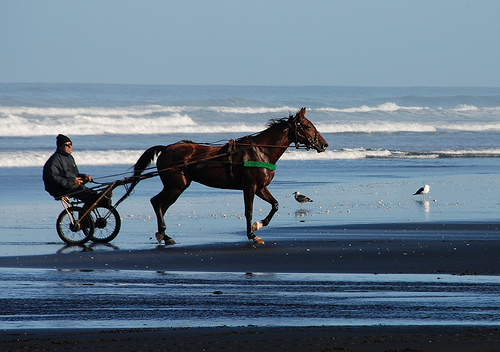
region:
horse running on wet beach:
[132, 110, 310, 242]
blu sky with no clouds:
[7, 12, 78, 56]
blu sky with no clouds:
[24, 53, 100, 69]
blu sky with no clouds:
[46, 20, 103, 82]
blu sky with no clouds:
[99, 10, 174, 60]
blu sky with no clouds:
[158, 40, 222, 70]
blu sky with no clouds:
[255, 20, 356, 91]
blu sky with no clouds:
[380, 12, 449, 47]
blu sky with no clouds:
[398, 3, 487, 74]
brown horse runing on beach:
[124, 105, 313, 237]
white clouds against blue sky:
[10, 12, 71, 41]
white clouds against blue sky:
[20, 37, 79, 74]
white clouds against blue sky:
[86, 17, 170, 67]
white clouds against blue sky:
[126, 57, 187, 71]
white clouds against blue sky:
[197, 9, 276, 62]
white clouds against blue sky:
[273, 7, 326, 34]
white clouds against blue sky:
[258, 54, 324, 92]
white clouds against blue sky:
[352, 3, 461, 36]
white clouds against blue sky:
[341, 46, 442, 82]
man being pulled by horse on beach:
[33, 89, 339, 256]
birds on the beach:
[286, 173, 444, 215]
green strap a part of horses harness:
[237, 151, 284, 176]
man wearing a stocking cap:
[49, 126, 77, 159]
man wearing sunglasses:
[50, 130, 78, 159]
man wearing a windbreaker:
[37, 150, 91, 200]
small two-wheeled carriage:
[42, 174, 159, 249]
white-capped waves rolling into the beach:
[0, 99, 142, 171]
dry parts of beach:
[279, 225, 486, 342]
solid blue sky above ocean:
[1, 4, 498, 99]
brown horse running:
[141, 124, 327, 238]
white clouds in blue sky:
[2, 12, 71, 42]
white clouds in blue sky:
[21, 42, 76, 65]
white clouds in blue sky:
[94, 9, 158, 49]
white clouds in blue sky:
[85, 43, 157, 63]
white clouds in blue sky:
[182, 18, 255, 65]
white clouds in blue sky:
[254, 16, 351, 55]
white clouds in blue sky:
[335, 13, 419, 46]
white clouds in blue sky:
[332, 50, 461, 77]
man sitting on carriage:
[25, 135, 122, 270]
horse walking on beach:
[132, 106, 328, 246]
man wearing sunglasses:
[40, 134, 101, 225]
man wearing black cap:
[41, 134, 98, 229]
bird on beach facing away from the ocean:
[412, 183, 435, 200]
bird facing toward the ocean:
[292, 189, 315, 212]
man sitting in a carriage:
[42, 134, 122, 246]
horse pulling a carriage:
[42, 104, 328, 246]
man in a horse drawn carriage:
[42, 107, 329, 246]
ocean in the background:
[1, 82, 498, 182]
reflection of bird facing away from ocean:
[414, 199, 432, 214]